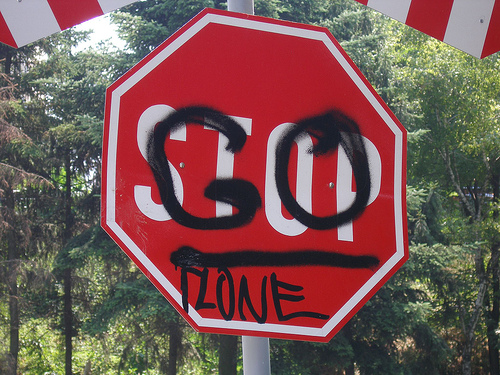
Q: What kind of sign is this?
A: A stop sign.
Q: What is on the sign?
A: Graffiti.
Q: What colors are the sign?
A: Red and white.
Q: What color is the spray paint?
A: Black.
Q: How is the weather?
A: Sunny.